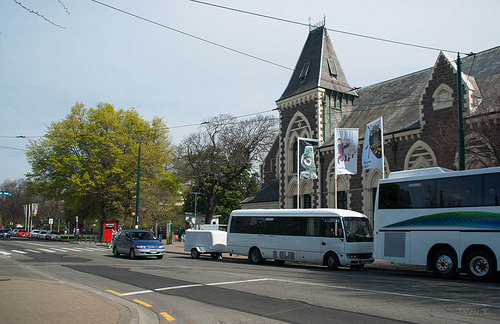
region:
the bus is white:
[197, 194, 384, 281]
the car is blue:
[101, 215, 165, 256]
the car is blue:
[101, 210, 201, 273]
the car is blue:
[71, 208, 166, 268]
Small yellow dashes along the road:
[109, 285, 181, 322]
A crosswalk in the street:
[0, 244, 107, 262]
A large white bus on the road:
[375, 179, 498, 286]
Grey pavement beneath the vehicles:
[150, 258, 315, 284]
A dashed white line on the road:
[128, 277, 277, 296]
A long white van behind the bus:
[215, 198, 382, 260]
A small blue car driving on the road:
[116, 227, 166, 258]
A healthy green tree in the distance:
[37, 108, 174, 218]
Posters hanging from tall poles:
[296, 118, 390, 180]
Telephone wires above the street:
[102, 3, 289, 65]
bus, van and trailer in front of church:
[181, 10, 496, 276]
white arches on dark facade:
[272, 30, 494, 215]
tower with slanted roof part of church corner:
[275, 20, 347, 205]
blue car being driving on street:
[107, 225, 487, 315]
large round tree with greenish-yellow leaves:
[25, 95, 185, 240]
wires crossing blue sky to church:
[5, 0, 495, 160]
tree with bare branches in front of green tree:
[180, 111, 277, 217]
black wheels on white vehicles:
[185, 165, 495, 275]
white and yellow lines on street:
[5, 240, 490, 320]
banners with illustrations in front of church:
[291, 113, 386, 208]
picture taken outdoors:
[14, 14, 492, 269]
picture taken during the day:
[25, 31, 443, 315]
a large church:
[271, 51, 486, 143]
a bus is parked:
[367, 155, 489, 279]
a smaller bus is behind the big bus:
[212, 193, 366, 263]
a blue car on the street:
[108, 224, 165, 261]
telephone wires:
[241, 4, 489, 162]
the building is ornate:
[265, 50, 492, 146]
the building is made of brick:
[260, 83, 330, 179]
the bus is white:
[247, 235, 342, 253]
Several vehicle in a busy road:
[0, 166, 499, 281]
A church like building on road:
[240, 12, 497, 247]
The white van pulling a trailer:
[184, 210, 375, 266]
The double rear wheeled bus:
[374, 166, 498, 283]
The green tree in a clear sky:
[1, 0, 278, 235]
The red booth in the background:
[101, 216, 114, 241]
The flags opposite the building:
[296, 118, 383, 213]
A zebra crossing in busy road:
[1, 241, 116, 256]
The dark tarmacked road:
[0, 235, 497, 321]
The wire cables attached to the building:
[92, 0, 474, 76]